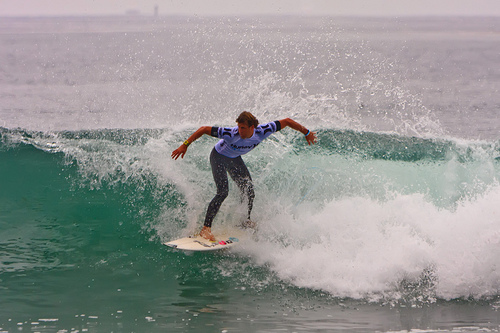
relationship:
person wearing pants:
[172, 114, 317, 240] [204, 148, 254, 225]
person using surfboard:
[172, 114, 317, 240] [162, 227, 259, 251]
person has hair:
[172, 114, 317, 240] [235, 111, 263, 129]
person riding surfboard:
[172, 114, 317, 240] [162, 227, 259, 251]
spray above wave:
[156, 40, 433, 129] [14, 126, 495, 286]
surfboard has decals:
[162, 227, 259, 251] [195, 238, 248, 247]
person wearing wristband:
[172, 114, 317, 240] [181, 138, 191, 148]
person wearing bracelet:
[172, 114, 317, 240] [304, 129, 311, 137]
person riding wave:
[172, 114, 317, 240] [14, 126, 495, 286]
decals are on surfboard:
[195, 238, 248, 247] [162, 227, 259, 251]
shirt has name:
[208, 124, 283, 157] [233, 143, 254, 149]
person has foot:
[172, 114, 317, 240] [199, 225, 216, 244]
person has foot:
[172, 114, 317, 240] [238, 216, 267, 232]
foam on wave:
[281, 189, 497, 296] [14, 126, 495, 286]